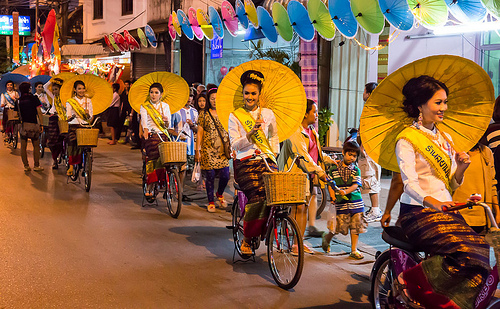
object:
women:
[192, 87, 231, 213]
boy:
[319, 141, 367, 259]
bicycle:
[224, 151, 311, 291]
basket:
[257, 172, 307, 207]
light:
[434, 22, 499, 40]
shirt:
[14, 93, 42, 125]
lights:
[230, 26, 254, 39]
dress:
[393, 202, 496, 308]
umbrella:
[304, 0, 337, 42]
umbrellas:
[217, 0, 239, 39]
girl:
[392, 74, 499, 309]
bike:
[368, 200, 497, 308]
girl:
[228, 71, 283, 258]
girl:
[137, 79, 175, 204]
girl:
[65, 80, 96, 177]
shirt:
[325, 157, 365, 215]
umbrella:
[40, 9, 58, 62]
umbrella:
[255, 5, 277, 44]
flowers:
[242, 71, 264, 87]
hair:
[238, 70, 263, 88]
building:
[83, 0, 174, 82]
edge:
[99, 130, 137, 149]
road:
[3, 16, 265, 115]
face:
[342, 151, 359, 164]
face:
[428, 90, 448, 123]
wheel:
[266, 216, 303, 290]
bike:
[138, 127, 184, 218]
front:
[154, 128, 185, 218]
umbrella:
[217, 59, 308, 144]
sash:
[393, 126, 450, 188]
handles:
[242, 154, 278, 172]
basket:
[160, 141, 189, 168]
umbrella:
[375, 1, 412, 34]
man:
[15, 83, 44, 172]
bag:
[22, 119, 40, 139]